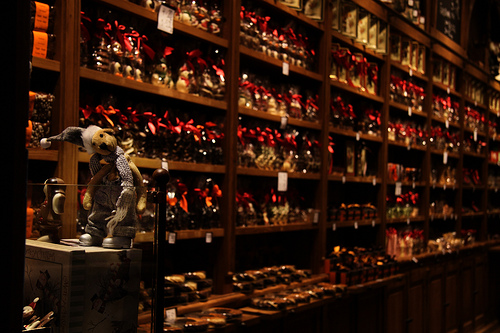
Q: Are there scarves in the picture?
A: Yes, there is a scarf.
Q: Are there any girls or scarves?
A: Yes, there is a scarf.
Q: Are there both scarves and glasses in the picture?
A: Yes, there are both a scarf and glasses.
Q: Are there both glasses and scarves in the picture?
A: Yes, there are both a scarf and glasses.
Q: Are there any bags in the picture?
A: No, there are no bags.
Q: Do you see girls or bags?
A: No, there are no bags or girls.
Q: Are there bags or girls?
A: No, there are no bags or girls.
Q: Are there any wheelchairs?
A: No, there are no wheelchairs.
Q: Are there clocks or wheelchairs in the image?
A: No, there are no wheelchairs or clocks.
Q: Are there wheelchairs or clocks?
A: No, there are no wheelchairs or clocks.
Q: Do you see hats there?
A: Yes, there is a hat.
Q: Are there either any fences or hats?
A: Yes, there is a hat.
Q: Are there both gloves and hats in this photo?
A: No, there is a hat but no gloves.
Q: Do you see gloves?
A: No, there are no gloves.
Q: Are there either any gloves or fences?
A: No, there are no gloves or fences.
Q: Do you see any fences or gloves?
A: No, there are no gloves or fences.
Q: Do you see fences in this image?
A: No, there are no fences.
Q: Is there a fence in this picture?
A: No, there are no fences.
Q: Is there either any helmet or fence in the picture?
A: No, there are no fences or helmets.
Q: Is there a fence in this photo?
A: No, there are no fences.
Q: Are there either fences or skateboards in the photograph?
A: No, there are no fences or skateboards.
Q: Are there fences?
A: No, there are no fences.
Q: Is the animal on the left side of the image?
A: Yes, the animal is on the left of the image.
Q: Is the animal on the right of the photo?
A: No, the animal is on the left of the image.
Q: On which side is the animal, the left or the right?
A: The animal is on the left of the image.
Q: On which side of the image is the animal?
A: The animal is on the left of the image.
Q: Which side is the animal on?
A: The animal is on the left of the image.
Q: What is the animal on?
A: The animal is on the glass.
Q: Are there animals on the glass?
A: Yes, there is an animal on the glass.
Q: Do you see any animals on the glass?
A: Yes, there is an animal on the glass.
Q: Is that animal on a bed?
A: No, the animal is on the glass.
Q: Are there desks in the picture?
A: No, there are no desks.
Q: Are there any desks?
A: No, there are no desks.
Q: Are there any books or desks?
A: No, there are no desks or books.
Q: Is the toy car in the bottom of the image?
A: Yes, the toy car is in the bottom of the image.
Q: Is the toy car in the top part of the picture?
A: No, the toy car is in the bottom of the image.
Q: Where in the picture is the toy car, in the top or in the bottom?
A: The toy car is in the bottom of the image.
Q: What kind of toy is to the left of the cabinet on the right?
A: The toy is a toy car.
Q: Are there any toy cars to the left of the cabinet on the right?
A: Yes, there is a toy car to the left of the cabinet.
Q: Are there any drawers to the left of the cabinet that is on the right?
A: No, there is a toy car to the left of the cabinet.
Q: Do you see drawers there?
A: No, there are no drawers.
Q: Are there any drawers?
A: No, there are no drawers.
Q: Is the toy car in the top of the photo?
A: No, the toy car is in the bottom of the image.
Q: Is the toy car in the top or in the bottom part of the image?
A: The toy car is in the bottom of the image.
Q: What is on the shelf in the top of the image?
A: The paper is on the shelf.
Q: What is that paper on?
A: The paper is on the shelf.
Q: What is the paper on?
A: The paper is on the shelf.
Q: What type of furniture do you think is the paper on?
A: The paper is on the shelf.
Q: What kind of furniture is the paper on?
A: The paper is on the shelf.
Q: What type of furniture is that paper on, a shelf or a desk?
A: The paper is on a shelf.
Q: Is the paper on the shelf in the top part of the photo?
A: Yes, the paper is on the shelf.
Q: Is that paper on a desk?
A: No, the paper is on the shelf.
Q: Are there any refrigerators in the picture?
A: No, there are no refrigerators.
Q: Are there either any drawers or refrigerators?
A: No, there are no refrigerators or drawers.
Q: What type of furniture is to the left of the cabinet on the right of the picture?
A: The piece of furniture is a shelf.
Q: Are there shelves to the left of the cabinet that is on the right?
A: Yes, there is a shelf to the left of the cabinet.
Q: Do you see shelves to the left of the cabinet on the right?
A: Yes, there is a shelf to the left of the cabinet.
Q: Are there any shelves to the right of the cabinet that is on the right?
A: No, the shelf is to the left of the cabinet.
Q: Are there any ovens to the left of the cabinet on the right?
A: No, there is a shelf to the left of the cabinet.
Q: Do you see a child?
A: No, there are no children.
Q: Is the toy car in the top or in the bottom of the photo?
A: The toy car is in the bottom of the image.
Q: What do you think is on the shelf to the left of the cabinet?
A: The toy car is on the shelf.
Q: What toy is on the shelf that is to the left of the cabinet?
A: The toy is a toy car.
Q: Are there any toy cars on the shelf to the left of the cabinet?
A: Yes, there is a toy car on the shelf.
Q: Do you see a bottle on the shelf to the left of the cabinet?
A: No, there is a toy car on the shelf.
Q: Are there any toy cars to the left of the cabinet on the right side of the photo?
A: Yes, there is a toy car to the left of the cabinet.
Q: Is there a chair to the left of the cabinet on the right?
A: No, there is a toy car to the left of the cabinet.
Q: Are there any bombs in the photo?
A: No, there are no bombs.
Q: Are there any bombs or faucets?
A: No, there are no bombs or faucets.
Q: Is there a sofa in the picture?
A: No, there are no sofas.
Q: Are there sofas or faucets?
A: No, there are no sofas or faucets.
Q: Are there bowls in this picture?
A: No, there are no bowls.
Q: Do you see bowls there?
A: No, there are no bowls.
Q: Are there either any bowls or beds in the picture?
A: No, there are no bowls or beds.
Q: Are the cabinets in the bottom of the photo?
A: Yes, the cabinets are in the bottom of the image.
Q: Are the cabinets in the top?
A: No, the cabinets are in the bottom of the image.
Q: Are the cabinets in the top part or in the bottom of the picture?
A: The cabinets are in the bottom of the image.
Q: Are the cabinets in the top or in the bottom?
A: The cabinets are in the bottom of the image.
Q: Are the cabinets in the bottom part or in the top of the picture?
A: The cabinets are in the bottom of the image.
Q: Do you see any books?
A: No, there are no books.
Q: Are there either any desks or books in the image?
A: No, there are no books or desks.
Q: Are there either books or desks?
A: No, there are no books or desks.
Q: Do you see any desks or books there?
A: No, there are no books or desks.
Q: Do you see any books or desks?
A: No, there are no books or desks.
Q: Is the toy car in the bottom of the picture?
A: Yes, the toy car is in the bottom of the image.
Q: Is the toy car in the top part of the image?
A: No, the toy car is in the bottom of the image.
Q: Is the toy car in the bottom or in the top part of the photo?
A: The toy car is in the bottom of the image.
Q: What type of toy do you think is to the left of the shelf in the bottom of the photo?
A: The toy is a toy car.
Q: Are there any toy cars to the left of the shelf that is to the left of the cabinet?
A: Yes, there is a toy car to the left of the shelf.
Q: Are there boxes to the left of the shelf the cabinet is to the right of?
A: No, there is a toy car to the left of the shelf.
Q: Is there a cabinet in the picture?
A: Yes, there is a cabinet.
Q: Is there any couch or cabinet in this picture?
A: Yes, there is a cabinet.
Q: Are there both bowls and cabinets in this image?
A: No, there is a cabinet but no bowls.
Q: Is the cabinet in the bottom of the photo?
A: Yes, the cabinet is in the bottom of the image.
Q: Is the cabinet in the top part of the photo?
A: No, the cabinet is in the bottom of the image.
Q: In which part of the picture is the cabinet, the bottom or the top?
A: The cabinet is in the bottom of the image.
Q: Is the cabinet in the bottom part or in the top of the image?
A: The cabinet is in the bottom of the image.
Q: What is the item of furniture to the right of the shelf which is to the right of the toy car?
A: The piece of furniture is a cabinet.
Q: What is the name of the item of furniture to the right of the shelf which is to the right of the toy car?
A: The piece of furniture is a cabinet.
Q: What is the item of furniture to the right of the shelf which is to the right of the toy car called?
A: The piece of furniture is a cabinet.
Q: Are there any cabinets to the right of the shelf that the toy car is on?
A: Yes, there is a cabinet to the right of the shelf.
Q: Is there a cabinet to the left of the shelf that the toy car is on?
A: No, the cabinet is to the right of the shelf.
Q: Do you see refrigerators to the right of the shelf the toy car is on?
A: No, there is a cabinet to the right of the shelf.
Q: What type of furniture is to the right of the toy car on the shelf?
A: The piece of furniture is a cabinet.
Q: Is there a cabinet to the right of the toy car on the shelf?
A: Yes, there is a cabinet to the right of the toy car.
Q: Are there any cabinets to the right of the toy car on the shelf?
A: Yes, there is a cabinet to the right of the toy car.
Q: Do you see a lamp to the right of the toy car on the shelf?
A: No, there is a cabinet to the right of the toy car.